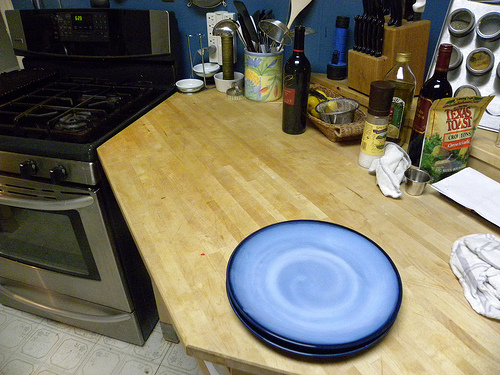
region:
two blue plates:
[216, 189, 380, 371]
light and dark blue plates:
[158, 170, 443, 373]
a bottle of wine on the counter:
[273, 22, 335, 143]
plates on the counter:
[182, 189, 411, 368]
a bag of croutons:
[390, 53, 499, 164]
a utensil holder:
[216, 2, 316, 114]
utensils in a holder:
[211, 7, 326, 109]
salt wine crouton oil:
[344, 28, 497, 145]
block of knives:
[329, 7, 447, 97]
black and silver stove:
[11, 2, 180, 297]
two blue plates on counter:
[187, 199, 407, 361]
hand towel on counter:
[450, 213, 498, 319]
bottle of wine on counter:
[276, 18, 319, 138]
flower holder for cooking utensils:
[235, 4, 290, 109]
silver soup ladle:
[205, 10, 253, 69]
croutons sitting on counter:
[419, 67, 483, 196]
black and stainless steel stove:
[10, 15, 148, 347]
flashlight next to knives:
[322, 8, 351, 84]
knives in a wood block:
[345, 3, 422, 90]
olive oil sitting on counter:
[377, 46, 415, 146]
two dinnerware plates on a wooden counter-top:
[225, 217, 401, 358]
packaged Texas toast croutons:
[419, 95, 494, 172]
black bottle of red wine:
[280, 26, 311, 135]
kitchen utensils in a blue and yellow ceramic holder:
[231, 1, 311, 101]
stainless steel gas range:
[1, 9, 176, 345]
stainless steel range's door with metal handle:
[2, 185, 137, 312]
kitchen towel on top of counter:
[447, 232, 499, 322]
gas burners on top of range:
[2, 82, 106, 135]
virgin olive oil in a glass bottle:
[385, 51, 417, 145]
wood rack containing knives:
[347, 0, 429, 97]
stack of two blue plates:
[222, 215, 414, 367]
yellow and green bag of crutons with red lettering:
[413, 83, 498, 188]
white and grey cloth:
[446, 228, 498, 323]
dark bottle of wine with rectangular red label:
[277, 22, 314, 142]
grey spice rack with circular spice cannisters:
[422, 0, 499, 135]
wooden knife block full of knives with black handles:
[345, 0, 434, 98]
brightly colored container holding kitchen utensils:
[228, 5, 292, 108]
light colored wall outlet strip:
[199, 6, 239, 68]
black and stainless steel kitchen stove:
[1, 5, 176, 345]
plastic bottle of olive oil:
[379, 42, 419, 148]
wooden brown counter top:
[115, 100, 411, 336]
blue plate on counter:
[189, 234, 389, 356]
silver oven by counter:
[0, 47, 172, 317]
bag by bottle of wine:
[417, 85, 497, 190]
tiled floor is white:
[3, 310, 149, 373]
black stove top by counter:
[15, 64, 170, 170]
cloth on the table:
[432, 224, 495, 302]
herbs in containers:
[457, 10, 497, 142]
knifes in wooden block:
[288, 26, 470, 113]